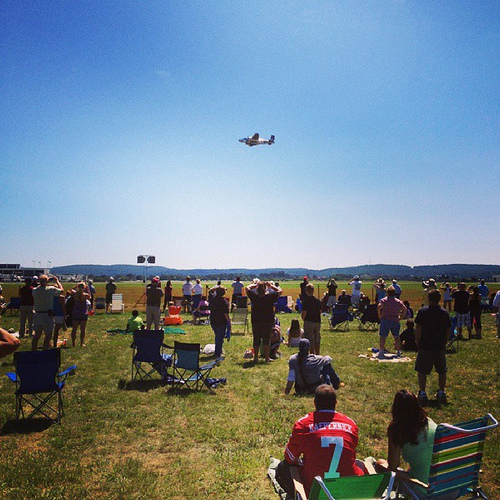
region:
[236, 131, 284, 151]
Plane flying in sky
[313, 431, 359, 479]
Number 7 on back of shirt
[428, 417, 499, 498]
Back of colorful lounge chair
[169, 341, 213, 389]
Back of lounge chair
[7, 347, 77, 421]
Back of blue chair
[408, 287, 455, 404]
Person standing in field area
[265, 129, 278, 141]
Tail of flying plane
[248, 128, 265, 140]
Wing of flying plane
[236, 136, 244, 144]
Nose of flying plane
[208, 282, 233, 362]
Person watching plane in sky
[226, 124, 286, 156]
A plane is in the air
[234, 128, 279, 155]
A side view of a plane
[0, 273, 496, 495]
A crowd of people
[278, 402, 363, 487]
Man is wearing a red jersery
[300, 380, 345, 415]
Man in the foreground has short hair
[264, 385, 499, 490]
Man and woman are sitting down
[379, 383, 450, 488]
Woman has dark colored hair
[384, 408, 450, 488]
Woman is wearing a green shirt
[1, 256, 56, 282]
A building in the background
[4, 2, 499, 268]
The sky is clear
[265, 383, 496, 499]
Two people sitting in chairs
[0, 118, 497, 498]
Air show on a sunny day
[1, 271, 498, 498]
People watching an airshow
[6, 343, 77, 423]
Foldable blue sport chair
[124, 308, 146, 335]
Person in green sitting on the ground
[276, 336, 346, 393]
Man sitting on the ground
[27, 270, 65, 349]
Man using a camera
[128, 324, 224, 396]
Two blue folding chairs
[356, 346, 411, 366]
Blanket on the ground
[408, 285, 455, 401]
Man standing with his hands in his pocket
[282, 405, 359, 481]
a man's red jersey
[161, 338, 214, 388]
a blue portable chair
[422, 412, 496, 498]
a colorful lawn chair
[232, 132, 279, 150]
a small plane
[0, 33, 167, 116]
part of a clear blue sky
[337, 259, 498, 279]
part of a mountain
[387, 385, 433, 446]
a woman's long brown hair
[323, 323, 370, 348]
a section of green grass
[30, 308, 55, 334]
a man's blue jean shorts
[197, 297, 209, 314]
a woman's pink shirt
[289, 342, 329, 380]
a person in crowd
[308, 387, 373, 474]
a person in crowd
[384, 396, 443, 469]
a person in crowd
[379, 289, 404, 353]
a person in crowd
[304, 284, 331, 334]
a person in crowd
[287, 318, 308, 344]
a person in crowd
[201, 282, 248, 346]
a person in crowd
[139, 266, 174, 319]
a person in crowd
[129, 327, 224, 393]
blue camp camp chair next to camp chair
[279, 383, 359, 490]
man wearing a red jersey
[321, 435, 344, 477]
number printed on jersey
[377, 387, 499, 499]
woman sitting in a a striped chair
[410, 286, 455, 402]
man standing on top of a field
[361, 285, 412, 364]
person standing on top of blanket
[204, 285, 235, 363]
person watching airplane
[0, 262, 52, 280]
building behind field